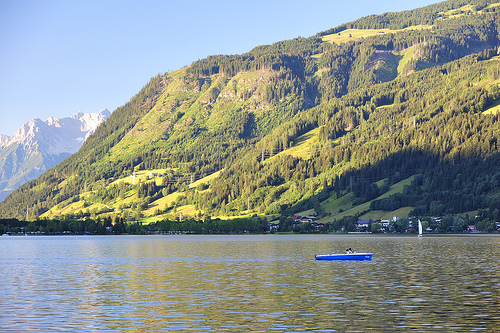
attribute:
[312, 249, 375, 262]
boat — blue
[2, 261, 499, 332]
water — in the area, dark, calm, still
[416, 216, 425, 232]
sail — white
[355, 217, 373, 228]
house — in the background, white, grey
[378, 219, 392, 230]
house — in the background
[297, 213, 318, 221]
house — in the background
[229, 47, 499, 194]
mountain — in the background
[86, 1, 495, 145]
mountain — in the background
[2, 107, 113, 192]
mountain — in the background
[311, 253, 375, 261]
boat — blue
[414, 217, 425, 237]
sailboat — white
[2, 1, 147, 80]
sky — blue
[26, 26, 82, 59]
clouds — white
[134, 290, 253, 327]
ripples — big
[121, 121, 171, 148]
grass — green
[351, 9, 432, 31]
trees — green